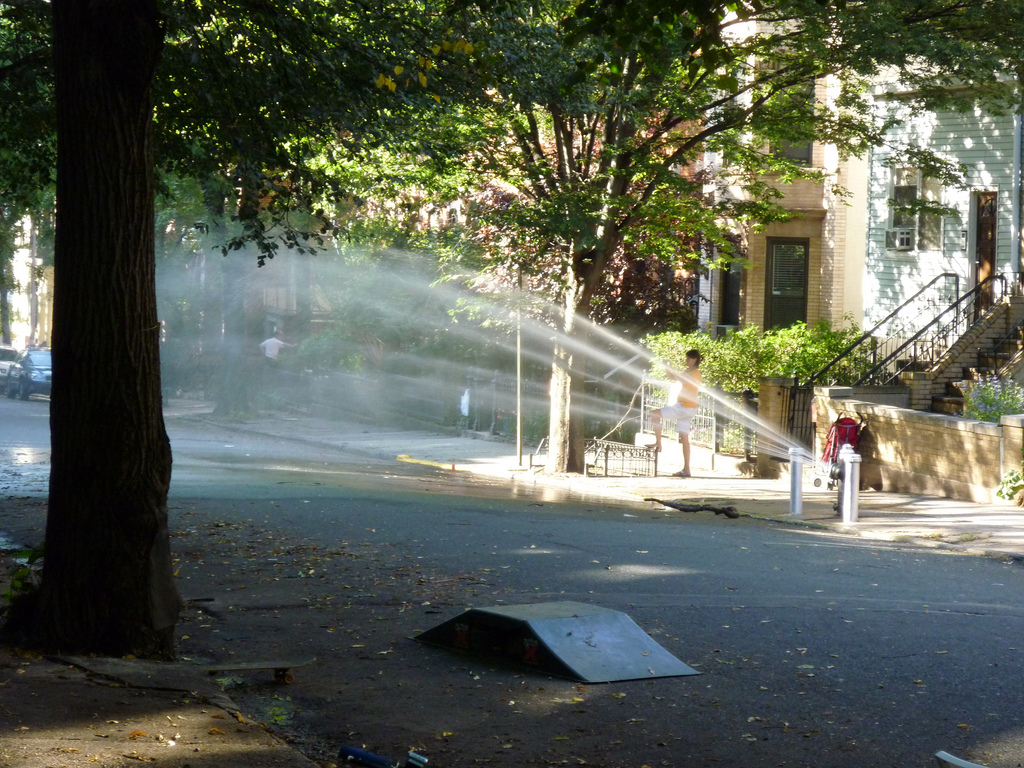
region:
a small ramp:
[417, 587, 703, 696]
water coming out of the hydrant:
[158, 227, 845, 494]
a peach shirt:
[678, 366, 704, 418]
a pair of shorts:
[654, 399, 699, 434]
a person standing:
[645, 344, 709, 477]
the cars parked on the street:
[5, 345, 51, 412]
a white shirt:
[258, 333, 285, 359]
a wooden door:
[969, 189, 999, 314]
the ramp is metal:
[454, 582, 708, 729]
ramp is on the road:
[427, 555, 759, 753]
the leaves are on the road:
[191, 510, 474, 648]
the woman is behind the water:
[637, 317, 724, 498]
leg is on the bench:
[634, 408, 672, 459]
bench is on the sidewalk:
[588, 421, 696, 491]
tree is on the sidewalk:
[418, 114, 649, 463]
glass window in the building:
[768, 240, 801, 329]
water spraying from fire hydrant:
[336, 245, 532, 446]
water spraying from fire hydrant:
[839, 443, 868, 533]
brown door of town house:
[764, 230, 816, 317]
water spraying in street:
[261, 285, 386, 447]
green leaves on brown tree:
[270, 24, 354, 126]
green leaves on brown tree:
[549, 78, 740, 265]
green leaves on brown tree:
[144, 24, 297, 272]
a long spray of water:
[163, 203, 844, 495]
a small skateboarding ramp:
[413, 584, 702, 699]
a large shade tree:
[8, 10, 563, 671]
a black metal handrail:
[799, 269, 1009, 448]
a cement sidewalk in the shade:
[0, 544, 310, 766]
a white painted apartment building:
[694, 9, 1018, 515]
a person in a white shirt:
[255, 329, 300, 406]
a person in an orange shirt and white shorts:
[650, 345, 720, 500]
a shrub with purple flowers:
[954, 366, 1022, 437]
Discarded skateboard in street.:
[186, 648, 320, 696]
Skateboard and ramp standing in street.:
[182, 585, 711, 699]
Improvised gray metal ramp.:
[407, 589, 703, 694]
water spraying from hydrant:
[283, 251, 869, 556]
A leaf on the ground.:
[748, 709, 767, 720]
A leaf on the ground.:
[749, 724, 766, 740]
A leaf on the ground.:
[795, 664, 809, 675]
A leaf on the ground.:
[796, 646, 810, 659]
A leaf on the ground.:
[827, 662, 847, 679]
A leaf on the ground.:
[913, 674, 933, 684]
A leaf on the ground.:
[356, 642, 369, 658]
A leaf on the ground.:
[246, 538, 250, 548]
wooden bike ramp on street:
[416, 589, 699, 689]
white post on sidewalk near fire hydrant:
[834, 443, 861, 536]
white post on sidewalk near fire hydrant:
[776, 443, 815, 523]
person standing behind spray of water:
[633, 339, 719, 482]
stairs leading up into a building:
[794, 269, 1013, 440]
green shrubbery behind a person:
[646, 314, 869, 398]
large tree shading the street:
[2, 3, 692, 668]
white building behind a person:
[856, 14, 1021, 420]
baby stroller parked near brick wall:
[820, 405, 869, 485]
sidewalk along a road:
[169, 392, 1021, 569]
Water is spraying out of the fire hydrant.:
[446, 296, 858, 528]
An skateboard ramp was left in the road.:
[419, 569, 695, 688]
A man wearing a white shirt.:
[252, 310, 304, 374]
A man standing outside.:
[252, 326, 300, 385]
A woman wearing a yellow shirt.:
[666, 370, 706, 410]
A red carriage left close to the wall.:
[805, 402, 866, 453]